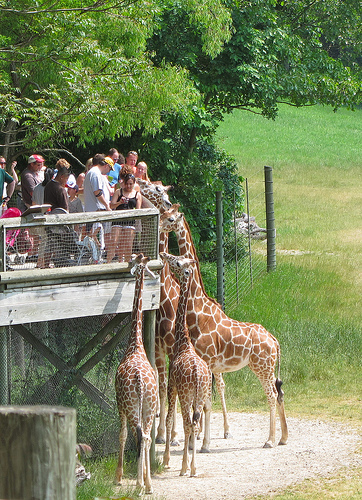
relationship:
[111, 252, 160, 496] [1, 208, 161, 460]
animal at fence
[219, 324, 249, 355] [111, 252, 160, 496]
spots on animal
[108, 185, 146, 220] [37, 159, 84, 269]
top on girl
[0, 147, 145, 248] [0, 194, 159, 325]
people on high platform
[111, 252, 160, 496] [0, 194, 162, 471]
animal by platform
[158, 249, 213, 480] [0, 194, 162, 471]
animal by platform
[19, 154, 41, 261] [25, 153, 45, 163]
man wearing hat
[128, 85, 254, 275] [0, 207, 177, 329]
trees behind platform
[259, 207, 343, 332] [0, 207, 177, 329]
weeds under platform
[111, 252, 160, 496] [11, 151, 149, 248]
animal beside people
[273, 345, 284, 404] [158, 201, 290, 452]
tail on animal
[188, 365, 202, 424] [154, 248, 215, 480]
tail on giraffe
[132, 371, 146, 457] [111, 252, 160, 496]
tail on animal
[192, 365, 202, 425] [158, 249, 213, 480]
tail on animal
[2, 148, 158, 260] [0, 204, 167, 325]
people on deck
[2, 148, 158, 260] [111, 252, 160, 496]
people looking at animal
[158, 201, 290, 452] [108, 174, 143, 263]
animal near people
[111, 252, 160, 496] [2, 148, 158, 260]
animal watching people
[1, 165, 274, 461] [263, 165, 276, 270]
fence has fence poles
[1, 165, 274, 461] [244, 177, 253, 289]
fence has fence poles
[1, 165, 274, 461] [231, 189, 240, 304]
fence has fence poles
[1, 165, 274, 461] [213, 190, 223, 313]
fence has fence poles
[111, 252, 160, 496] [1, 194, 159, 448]
animal near high platform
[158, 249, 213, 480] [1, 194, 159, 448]
animal near high platform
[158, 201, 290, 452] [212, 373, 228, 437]
animal has leg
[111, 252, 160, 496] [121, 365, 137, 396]
animal has brown spots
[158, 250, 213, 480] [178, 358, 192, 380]
animal has brown spots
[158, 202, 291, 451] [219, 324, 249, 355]
animal has spots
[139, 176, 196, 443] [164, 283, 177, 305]
animal has brown spots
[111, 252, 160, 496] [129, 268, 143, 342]
animal has neck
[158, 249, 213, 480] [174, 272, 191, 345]
animal has neck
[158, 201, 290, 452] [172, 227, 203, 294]
animal has neck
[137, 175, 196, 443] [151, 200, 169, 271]
animal has neck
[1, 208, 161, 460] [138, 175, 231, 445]
fence near animals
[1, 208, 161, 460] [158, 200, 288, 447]
fence near animals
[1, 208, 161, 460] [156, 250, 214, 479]
fence near animals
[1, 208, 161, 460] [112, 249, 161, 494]
fence near animals